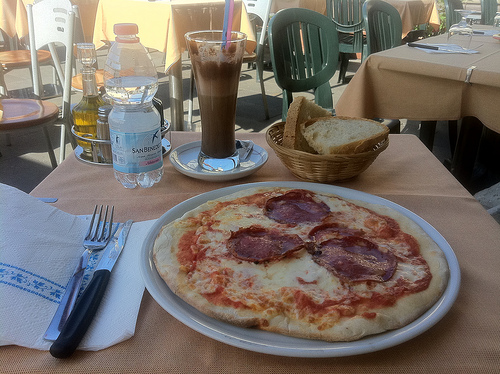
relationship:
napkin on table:
[0, 181, 158, 351] [0, 130, 499, 372]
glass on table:
[177, 23, 252, 163] [0, 130, 499, 372]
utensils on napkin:
[45, 198, 115, 341] [0, 181, 158, 351]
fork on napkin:
[38, 199, 129, 358] [0, 181, 158, 351]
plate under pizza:
[134, 176, 465, 362] [149, 183, 455, 346]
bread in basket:
[304, 111, 389, 151] [255, 110, 415, 182]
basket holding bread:
[273, 102, 375, 173] [285, 93, 391, 157]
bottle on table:
[104, 18, 166, 191] [0, 130, 499, 372]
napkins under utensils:
[3, 184, 60, 296] [42, 202, 134, 369]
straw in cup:
[229, 3, 241, 48] [180, 29, 237, 159]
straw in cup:
[222, 1, 229, 55] [180, 29, 237, 159]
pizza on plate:
[149, 183, 455, 346] [134, 176, 465, 362]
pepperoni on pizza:
[259, 189, 334, 224] [149, 183, 455, 346]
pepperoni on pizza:
[307, 227, 403, 284] [149, 183, 455, 346]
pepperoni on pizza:
[223, 223, 305, 265] [149, 183, 455, 346]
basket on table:
[265, 109, 388, 183] [22, 65, 464, 345]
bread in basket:
[304, 111, 389, 151] [265, 120, 390, 180]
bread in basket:
[284, 95, 334, 149] [265, 120, 390, 180]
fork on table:
[20, 191, 120, 358] [0, 107, 485, 371]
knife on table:
[45, 217, 133, 359] [374, 29, 497, 114]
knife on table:
[45, 217, 133, 359] [412, 135, 498, 369]